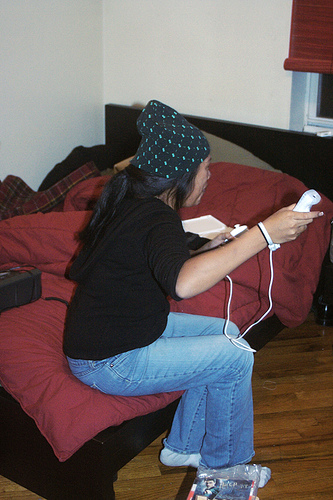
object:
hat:
[134, 94, 210, 176]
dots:
[158, 133, 163, 141]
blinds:
[283, 3, 331, 75]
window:
[283, 1, 330, 136]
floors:
[0, 327, 332, 500]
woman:
[63, 99, 278, 500]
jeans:
[67, 314, 258, 461]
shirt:
[64, 190, 188, 361]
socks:
[157, 445, 202, 470]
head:
[126, 100, 213, 211]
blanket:
[0, 161, 332, 456]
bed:
[1, 98, 329, 493]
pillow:
[213, 133, 275, 168]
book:
[185, 468, 256, 500]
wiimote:
[224, 181, 324, 262]